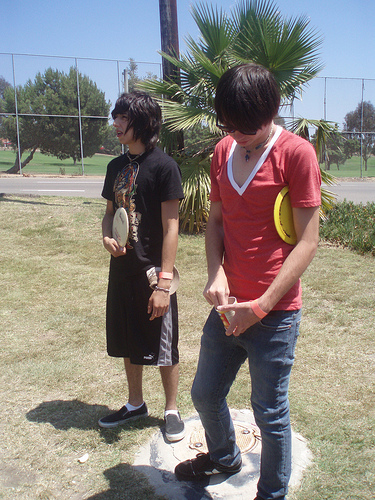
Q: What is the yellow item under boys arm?
A: Frisbee.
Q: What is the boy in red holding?
A: Cup.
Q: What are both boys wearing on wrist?
A: Orange bands.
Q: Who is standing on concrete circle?
A: Boy in red.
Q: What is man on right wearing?
A: Red shirt and jeans.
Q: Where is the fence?
A: Behind the boys around a park.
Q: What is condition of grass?
A: Dry and dying.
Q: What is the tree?
A: Palm tree.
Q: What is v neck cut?
A: The shirt.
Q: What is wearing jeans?
A: The man.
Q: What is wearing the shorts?
A: The man.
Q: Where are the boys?
A: Park.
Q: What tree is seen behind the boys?
A: Palm.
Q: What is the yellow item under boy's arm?
A: Frisbee.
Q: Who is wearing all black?
A: Shorter boy.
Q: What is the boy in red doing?
A: Dipping fingers in cup.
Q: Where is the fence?
A: Behind the boys.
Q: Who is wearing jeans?
A: Boy in red.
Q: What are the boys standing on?
A: Metal cover.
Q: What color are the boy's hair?
A: Black.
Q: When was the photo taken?
A: Daytime.